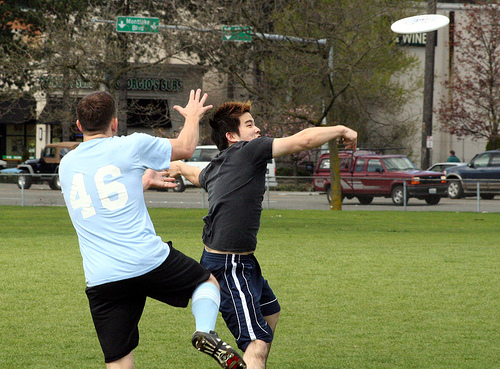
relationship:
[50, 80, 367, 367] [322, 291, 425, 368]
men playing field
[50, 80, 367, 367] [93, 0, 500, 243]
men playing frisbee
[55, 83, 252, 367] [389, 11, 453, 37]
man playing frisbee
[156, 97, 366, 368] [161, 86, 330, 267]
man wearing shirt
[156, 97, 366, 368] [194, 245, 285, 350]
man wearing shorts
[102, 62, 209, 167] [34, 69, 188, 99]
store with words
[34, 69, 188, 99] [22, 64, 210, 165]
words on top of building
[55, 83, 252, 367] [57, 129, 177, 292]
man wearing shirt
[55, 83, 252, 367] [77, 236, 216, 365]
man wearing shorts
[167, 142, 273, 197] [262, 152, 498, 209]
van parked in lot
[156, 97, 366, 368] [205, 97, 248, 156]
man with hair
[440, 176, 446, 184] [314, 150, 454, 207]
light of truck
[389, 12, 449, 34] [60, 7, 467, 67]
frisbee in air